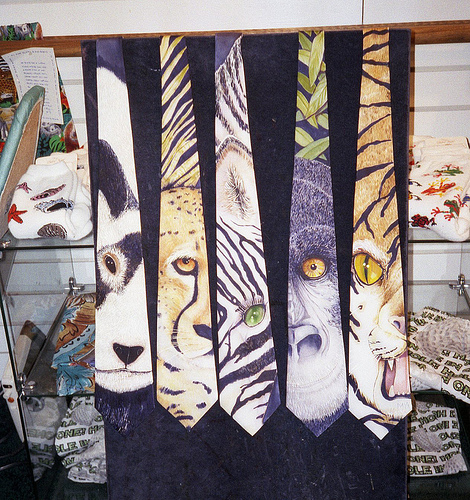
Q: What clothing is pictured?
A: Ties.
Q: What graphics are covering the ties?
A: Animals.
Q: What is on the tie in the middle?
A: A zebra.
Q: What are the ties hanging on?
A: A board.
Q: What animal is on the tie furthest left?
A: A panda.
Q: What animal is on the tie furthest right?
A: A tiger.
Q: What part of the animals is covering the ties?
A: Faces.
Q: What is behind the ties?
A: Blankets.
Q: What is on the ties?
A: Animals.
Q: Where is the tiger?
A: On tie.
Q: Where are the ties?
A: On blackboard.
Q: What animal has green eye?
A: Zebra.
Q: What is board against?
A: White wall.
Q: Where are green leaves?
A: On ape tie.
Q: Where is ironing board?
A: To left of photo.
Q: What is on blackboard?
A: Five ties.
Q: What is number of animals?
A: Five.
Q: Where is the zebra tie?
A: In the middle.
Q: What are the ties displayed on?
A: A blackboard.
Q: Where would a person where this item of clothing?
A: On their neck.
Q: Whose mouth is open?
A: The tigers.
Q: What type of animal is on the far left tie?
A: A panda.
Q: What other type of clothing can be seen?
A: T-shirts.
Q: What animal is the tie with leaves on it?
A: A gorilla.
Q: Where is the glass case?
A: Behind the ties.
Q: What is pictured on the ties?
A: Animals.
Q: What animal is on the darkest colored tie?
A: Panda Bear.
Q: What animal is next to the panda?
A: Cheetah.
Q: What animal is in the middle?
A: Zebra.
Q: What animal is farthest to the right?
A: Tiger.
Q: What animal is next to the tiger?
A: Gorilla.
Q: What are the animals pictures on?
A: Dress Ties.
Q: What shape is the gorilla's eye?
A: Round.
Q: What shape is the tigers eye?
A: Round.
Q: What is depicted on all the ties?
A: Animal faces.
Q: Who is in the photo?
A: Nobody.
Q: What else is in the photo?
A: Glass shelves.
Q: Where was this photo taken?
A: In a store room.